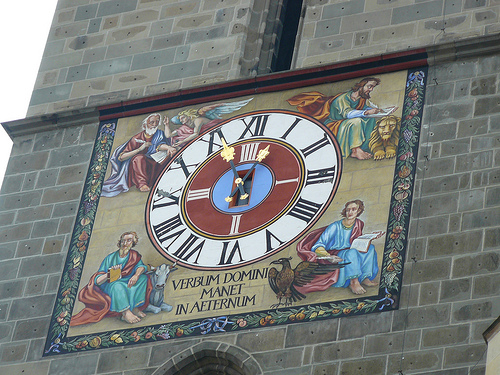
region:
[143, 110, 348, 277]
a clock with roman numerals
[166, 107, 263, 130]
a painting of an angel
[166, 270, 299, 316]
some french words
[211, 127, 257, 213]
the minute hand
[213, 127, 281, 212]
the hour hand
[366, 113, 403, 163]
a golden lion with nice hair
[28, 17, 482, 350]
a brick building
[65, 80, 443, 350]
a beautiful looking clock with roman numerals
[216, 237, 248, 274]
the roman numeral for 6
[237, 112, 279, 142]
the roman numeral for 12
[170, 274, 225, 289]
The word VERBUM on a clock face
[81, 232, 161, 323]
Man sitting holding a book on a clock face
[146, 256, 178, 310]
Cow laying down on a clock face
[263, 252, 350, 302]
Bird pointing wing to the right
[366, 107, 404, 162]
Lion laying down with paper on its head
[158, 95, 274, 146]
Angel with wings pointing up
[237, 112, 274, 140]
Roman numeral for twelve on a clock face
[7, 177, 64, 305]
Bricks of a building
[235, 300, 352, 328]
Flower design painted on a clock face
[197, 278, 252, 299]
The word MANET on a clock face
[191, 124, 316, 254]
this is a clock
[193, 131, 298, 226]
the clock is white in color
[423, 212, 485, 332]
this is a wall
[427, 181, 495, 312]
the wall is made of stone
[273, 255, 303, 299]
this is a bird drawing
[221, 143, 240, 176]
this is minute hand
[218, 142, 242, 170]
the minute hand is long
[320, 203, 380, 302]
this is a mans drawing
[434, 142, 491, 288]
the wall is old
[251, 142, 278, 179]
the hour hand is short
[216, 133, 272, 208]
gold and black hands of a clock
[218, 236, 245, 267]
upside down black roman numeral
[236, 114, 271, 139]
right side up black roman numeral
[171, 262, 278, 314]
phrase written in Latin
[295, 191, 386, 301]
a painted figure sitting down reading a book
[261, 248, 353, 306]
a bird showing off the length of one of its wings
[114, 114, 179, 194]
an old man with a big white beard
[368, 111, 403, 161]
a golden lion laying down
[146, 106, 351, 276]
a clock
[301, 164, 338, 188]
sideways black roman numerals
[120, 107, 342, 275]
the clock is on the side of the building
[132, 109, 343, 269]
the clock has roman numerals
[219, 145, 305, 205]
the clock has an hour hand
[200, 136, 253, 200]
the clock has a minute hand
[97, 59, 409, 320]
the clock has religious pictures painted next to it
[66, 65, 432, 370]
the clock has a square border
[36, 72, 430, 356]
the border is black with vines and flowers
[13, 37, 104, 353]
the building is made of brick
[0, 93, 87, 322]
the brick is brown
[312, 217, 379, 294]
the man's dress is blue